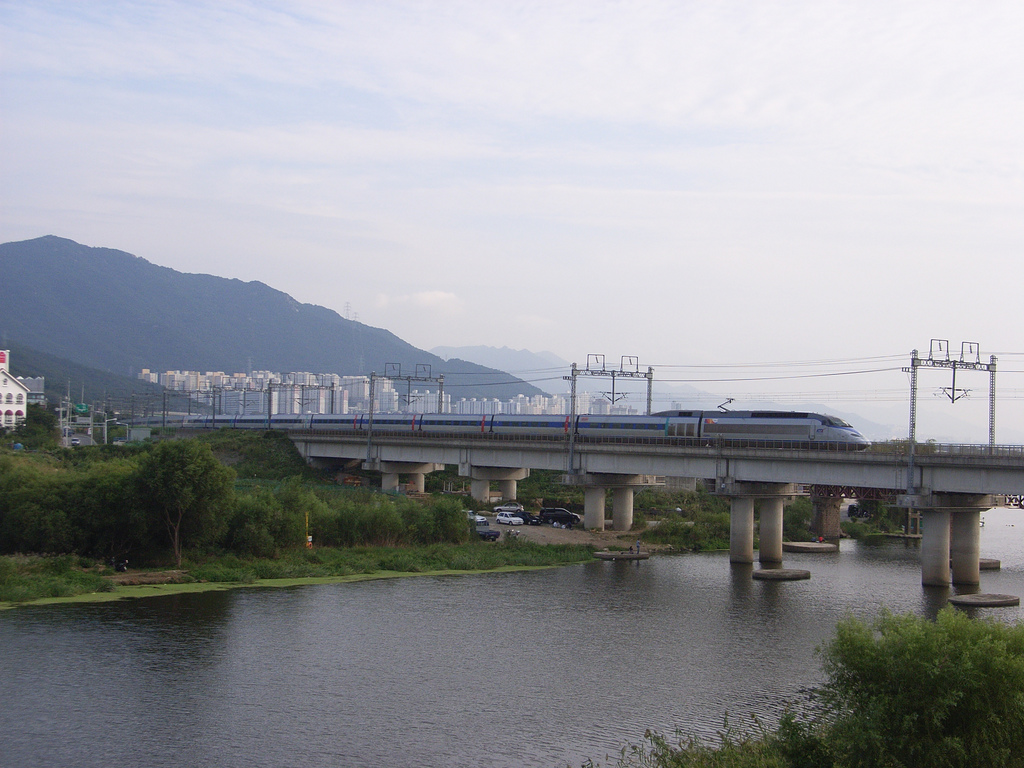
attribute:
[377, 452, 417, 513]
pillar — solid, tan, concrete, bridge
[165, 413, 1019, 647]
bridge — one, tan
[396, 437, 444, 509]
pillar — tan, solid, concrete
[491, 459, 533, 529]
pillar — concrete, tan, solid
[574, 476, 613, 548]
pillar — solid, concrete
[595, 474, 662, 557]
pillar — concrete, tan, solid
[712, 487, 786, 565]
pillar — solid, tan, concrete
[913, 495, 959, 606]
pillar — concrete, solid, tan